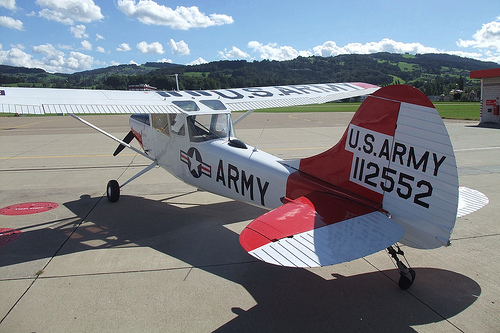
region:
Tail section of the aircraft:
[236, 82, 491, 270]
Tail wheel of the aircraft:
[383, 243, 420, 292]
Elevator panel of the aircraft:
[245, 207, 407, 269]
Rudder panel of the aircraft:
[381, 97, 460, 244]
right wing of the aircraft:
[220, 76, 382, 112]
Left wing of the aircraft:
[0, 85, 179, 118]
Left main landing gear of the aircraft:
[102, 159, 157, 204]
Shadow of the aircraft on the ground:
[1, 195, 482, 332]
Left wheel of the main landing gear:
[104, 177, 122, 203]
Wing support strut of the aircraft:
[63, 110, 155, 161]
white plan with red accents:
[7, 56, 494, 313]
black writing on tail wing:
[341, 74, 463, 246]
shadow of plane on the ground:
[9, 171, 484, 331]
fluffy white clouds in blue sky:
[5, 1, 495, 72]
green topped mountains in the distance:
[6, 45, 498, 113]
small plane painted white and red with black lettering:
[5, 68, 498, 293]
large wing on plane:
[2, 80, 391, 120]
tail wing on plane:
[234, 78, 487, 285]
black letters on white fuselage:
[175, 145, 282, 212]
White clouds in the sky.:
[61, 10, 232, 63]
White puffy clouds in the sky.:
[45, 15, 297, 85]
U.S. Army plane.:
[54, 88, 497, 307]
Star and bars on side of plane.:
[138, 139, 231, 186]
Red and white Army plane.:
[42, 82, 462, 314]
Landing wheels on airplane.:
[75, 130, 171, 245]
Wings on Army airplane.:
[5, 70, 415, 126]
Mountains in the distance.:
[35, 26, 350, 103]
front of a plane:
[92, 78, 239, 162]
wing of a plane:
[195, 192, 400, 293]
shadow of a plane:
[86, 189, 208, 289]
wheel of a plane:
[92, 156, 146, 226]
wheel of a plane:
[386, 266, 427, 288]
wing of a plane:
[2, 66, 122, 144]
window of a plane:
[176, 106, 226, 140]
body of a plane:
[169, 136, 311, 214]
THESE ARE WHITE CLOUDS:
[1, 0, 242, 34]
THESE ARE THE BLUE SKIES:
[2, 0, 497, 75]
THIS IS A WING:
[1, 83, 391, 116]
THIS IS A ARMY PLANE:
[0, 78, 497, 290]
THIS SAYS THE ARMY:
[210, 154, 270, 211]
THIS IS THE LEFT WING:
[235, 190, 406, 272]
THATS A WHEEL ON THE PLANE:
[390, 265, 422, 288]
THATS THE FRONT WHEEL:
[101, 176, 120, 207]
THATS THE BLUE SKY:
[2, 0, 497, 72]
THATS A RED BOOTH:
[472, 63, 497, 130]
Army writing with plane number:
[336, 114, 455, 214]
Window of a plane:
[183, 110, 231, 141]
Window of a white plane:
[185, 115, 235, 144]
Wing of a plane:
[234, 188, 407, 277]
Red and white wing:
[238, 195, 391, 273]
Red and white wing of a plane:
[230, 185, 404, 272]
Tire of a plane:
[103, 177, 122, 204]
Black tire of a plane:
[101, 175, 123, 205]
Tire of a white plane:
[103, 178, 123, 204]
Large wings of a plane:
[3, 78, 375, 121]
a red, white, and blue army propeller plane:
[0, 80, 489, 292]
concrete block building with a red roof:
[468, 67, 498, 124]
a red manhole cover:
[0, 200, 58, 215]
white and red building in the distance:
[127, 82, 158, 91]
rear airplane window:
[187, 114, 235, 142]